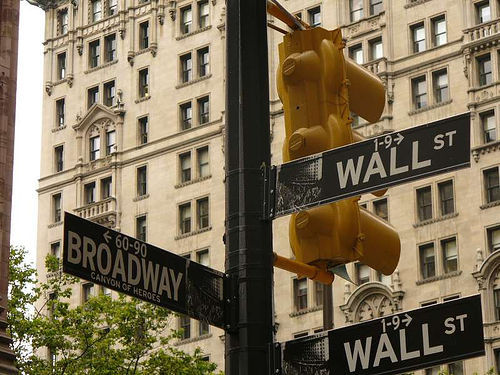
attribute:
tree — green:
[6, 242, 223, 373]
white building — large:
[71, 40, 250, 230]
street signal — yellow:
[276, 27, 403, 285]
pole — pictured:
[221, 2, 272, 373]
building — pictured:
[41, 2, 224, 210]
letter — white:
[328, 151, 374, 186]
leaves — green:
[40, 290, 162, 345]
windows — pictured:
[178, 89, 213, 132]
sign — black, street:
[50, 182, 238, 329]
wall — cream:
[88, 54, 260, 212]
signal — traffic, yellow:
[280, 15, 398, 288]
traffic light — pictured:
[271, 17, 386, 155]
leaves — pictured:
[29, 303, 179, 367]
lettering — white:
[64, 233, 184, 305]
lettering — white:
[339, 130, 464, 197]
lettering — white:
[340, 314, 472, 372]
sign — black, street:
[55, 208, 227, 338]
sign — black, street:
[264, 112, 474, 227]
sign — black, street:
[273, 292, 490, 372]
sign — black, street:
[270, 109, 477, 221]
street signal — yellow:
[263, 0, 407, 292]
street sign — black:
[270, 283, 489, 367]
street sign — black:
[264, 104, 474, 213]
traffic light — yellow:
[268, 0, 403, 281]